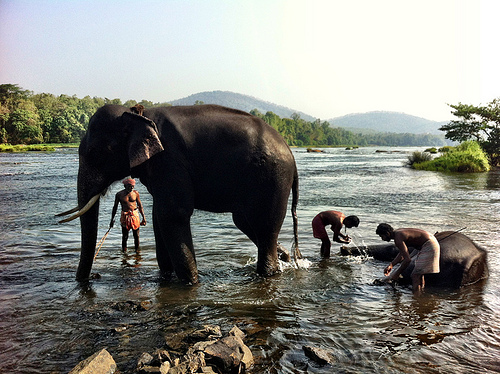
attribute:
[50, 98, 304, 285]
elephant — large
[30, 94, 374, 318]
elephant — large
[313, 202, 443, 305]
men — in water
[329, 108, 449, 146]
mountain — distant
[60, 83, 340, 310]
elephant — large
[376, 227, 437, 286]
man — bare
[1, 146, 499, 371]
river — calm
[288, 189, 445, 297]
men — bare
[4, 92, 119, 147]
trees — green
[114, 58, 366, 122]
peak — highest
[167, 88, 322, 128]
hill — back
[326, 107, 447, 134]
hill — back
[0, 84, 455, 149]
trees lines — linear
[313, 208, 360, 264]
man — splashing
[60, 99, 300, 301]
elephant — black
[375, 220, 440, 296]
man — in water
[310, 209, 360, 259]
man — in water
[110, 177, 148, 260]
man — in water